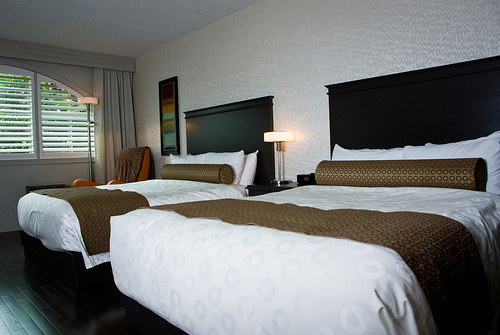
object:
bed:
[109, 133, 499, 333]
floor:
[0, 255, 110, 334]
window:
[0, 65, 100, 162]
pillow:
[399, 133, 499, 191]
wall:
[119, 3, 498, 179]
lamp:
[263, 129, 295, 186]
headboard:
[323, 53, 499, 161]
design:
[239, 16, 369, 68]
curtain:
[89, 63, 142, 184]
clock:
[293, 172, 318, 184]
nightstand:
[244, 176, 315, 202]